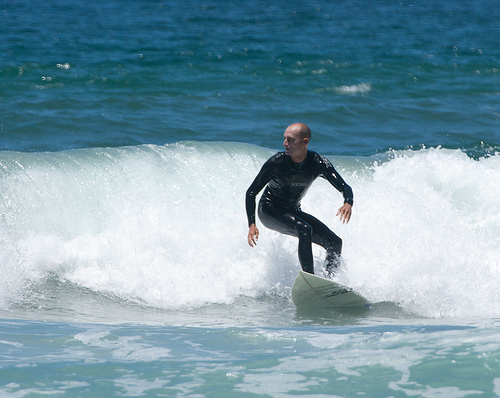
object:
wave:
[0, 144, 499, 336]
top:
[2, 139, 496, 182]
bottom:
[0, 262, 499, 321]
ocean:
[0, 0, 499, 396]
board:
[287, 266, 372, 319]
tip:
[288, 264, 322, 288]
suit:
[244, 152, 354, 283]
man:
[242, 120, 356, 281]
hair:
[282, 120, 313, 143]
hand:
[337, 200, 357, 221]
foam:
[69, 323, 176, 364]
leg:
[260, 203, 317, 275]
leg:
[301, 210, 343, 282]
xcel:
[287, 177, 313, 195]